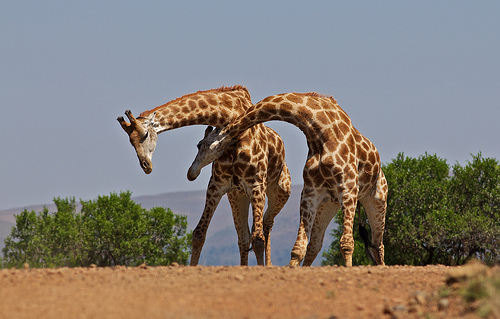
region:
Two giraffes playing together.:
[114, 84, 386, 266]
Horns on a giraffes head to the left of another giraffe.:
[112, 109, 136, 129]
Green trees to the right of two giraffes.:
[382, 155, 497, 264]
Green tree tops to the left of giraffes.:
[3, 195, 194, 268]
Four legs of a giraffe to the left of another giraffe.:
[287, 191, 387, 266]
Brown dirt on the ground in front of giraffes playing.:
[0, 261, 498, 318]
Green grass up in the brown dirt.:
[435, 274, 490, 306]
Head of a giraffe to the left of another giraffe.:
[117, 115, 155, 175]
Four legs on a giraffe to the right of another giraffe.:
[187, 175, 292, 265]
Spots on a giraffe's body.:
[321, 121, 352, 176]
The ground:
[108, 299, 208, 316]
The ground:
[222, 286, 305, 313]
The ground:
[316, 276, 371, 310]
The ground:
[287, 277, 347, 315]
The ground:
[262, 237, 342, 292]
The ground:
[176, 269, 264, 311]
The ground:
[225, 259, 327, 316]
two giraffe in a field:
[115, 61, 414, 270]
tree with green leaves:
[0, 180, 192, 285]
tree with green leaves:
[329, 143, 499, 272]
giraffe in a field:
[114, 85, 290, 269]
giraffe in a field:
[184, 83, 396, 273]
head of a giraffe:
[179, 121, 229, 185]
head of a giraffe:
[107, 98, 164, 178]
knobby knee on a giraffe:
[248, 227, 268, 252]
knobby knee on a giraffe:
[335, 233, 357, 258]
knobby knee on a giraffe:
[188, 219, 208, 251]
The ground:
[108, 277, 195, 314]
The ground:
[237, 291, 269, 303]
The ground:
[201, 248, 409, 315]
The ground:
[266, 290, 306, 307]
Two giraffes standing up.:
[102, 55, 400, 264]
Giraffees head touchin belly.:
[171, 117, 301, 185]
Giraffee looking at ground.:
[110, 106, 169, 181]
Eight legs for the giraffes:
[186, 187, 392, 270]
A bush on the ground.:
[0, 183, 192, 274]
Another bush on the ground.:
[378, 152, 499, 269]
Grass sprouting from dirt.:
[440, 275, 499, 317]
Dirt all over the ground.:
[29, 260, 394, 317]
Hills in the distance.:
[133, 186, 199, 213]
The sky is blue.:
[268, 21, 499, 88]